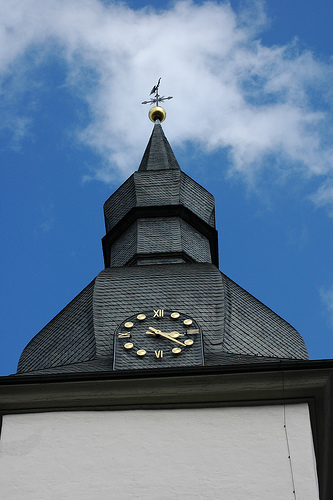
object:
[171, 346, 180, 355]
number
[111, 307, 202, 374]
clock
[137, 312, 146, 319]
number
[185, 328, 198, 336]
number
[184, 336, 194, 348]
number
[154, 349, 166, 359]
number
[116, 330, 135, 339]
number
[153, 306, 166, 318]
number